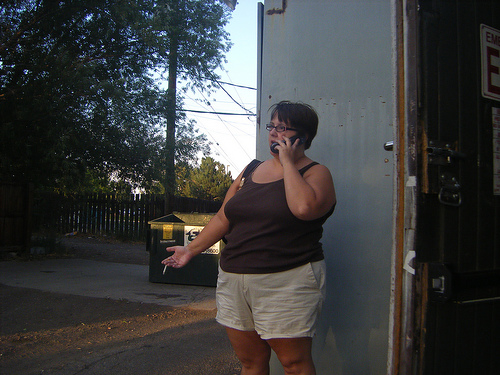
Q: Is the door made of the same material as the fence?
A: Yes, both the door and the fence are made of wood.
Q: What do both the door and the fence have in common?
A: The material, both the door and the fence are wooden.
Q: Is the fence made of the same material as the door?
A: Yes, both the fence and the door are made of wood.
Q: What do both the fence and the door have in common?
A: The material, both the fence and the door are wooden.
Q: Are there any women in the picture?
A: Yes, there is a woman.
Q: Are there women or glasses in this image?
A: Yes, there is a woman.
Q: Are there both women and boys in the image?
A: No, there is a woman but no boys.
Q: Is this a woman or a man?
A: This is a woman.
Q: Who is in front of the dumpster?
A: The woman is in front of the dumpster.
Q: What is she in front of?
A: The woman is in front of the dumpster.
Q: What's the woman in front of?
A: The woman is in front of the dumpster.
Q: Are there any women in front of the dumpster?
A: Yes, there is a woman in front of the dumpster.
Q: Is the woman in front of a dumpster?
A: Yes, the woman is in front of a dumpster.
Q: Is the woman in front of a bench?
A: No, the woman is in front of a dumpster.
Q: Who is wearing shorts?
A: The woman is wearing shorts.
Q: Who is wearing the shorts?
A: The woman is wearing shorts.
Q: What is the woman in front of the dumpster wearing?
A: The woman is wearing shorts.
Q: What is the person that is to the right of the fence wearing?
A: The woman is wearing shorts.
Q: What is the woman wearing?
A: The woman is wearing shorts.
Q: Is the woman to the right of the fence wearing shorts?
A: Yes, the woman is wearing shorts.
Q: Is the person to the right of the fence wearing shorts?
A: Yes, the woman is wearing shorts.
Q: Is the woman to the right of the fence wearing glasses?
A: No, the woman is wearing shorts.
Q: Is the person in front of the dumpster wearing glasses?
A: No, the woman is wearing shorts.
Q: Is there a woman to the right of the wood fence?
A: Yes, there is a woman to the right of the fence.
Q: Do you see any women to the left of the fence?
A: No, the woman is to the right of the fence.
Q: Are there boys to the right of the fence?
A: No, there is a woman to the right of the fence.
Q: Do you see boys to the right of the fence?
A: No, there is a woman to the right of the fence.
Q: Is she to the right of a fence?
A: Yes, the woman is to the right of a fence.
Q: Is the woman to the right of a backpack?
A: No, the woman is to the right of a fence.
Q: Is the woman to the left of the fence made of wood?
A: No, the woman is to the right of the fence.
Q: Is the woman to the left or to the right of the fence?
A: The woman is to the right of the fence.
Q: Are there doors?
A: Yes, there is a door.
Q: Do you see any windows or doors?
A: Yes, there is a door.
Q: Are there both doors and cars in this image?
A: No, there is a door but no cars.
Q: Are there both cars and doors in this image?
A: No, there is a door but no cars.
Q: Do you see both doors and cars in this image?
A: No, there is a door but no cars.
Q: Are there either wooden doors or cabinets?
A: Yes, there is a wood door.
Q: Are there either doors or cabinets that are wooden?
A: Yes, the door is wooden.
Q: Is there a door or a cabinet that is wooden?
A: Yes, the door is wooden.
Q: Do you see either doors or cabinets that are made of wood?
A: Yes, the door is made of wood.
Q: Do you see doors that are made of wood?
A: Yes, there is a door that is made of wood.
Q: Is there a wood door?
A: Yes, there is a door that is made of wood.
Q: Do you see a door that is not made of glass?
A: Yes, there is a door that is made of wood.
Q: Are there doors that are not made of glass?
A: Yes, there is a door that is made of wood.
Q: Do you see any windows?
A: No, there are no windows.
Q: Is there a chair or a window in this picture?
A: No, there are no windows or chairs.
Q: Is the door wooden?
A: Yes, the door is wooden.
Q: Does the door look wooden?
A: Yes, the door is wooden.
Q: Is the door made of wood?
A: Yes, the door is made of wood.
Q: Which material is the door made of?
A: The door is made of wood.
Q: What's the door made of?
A: The door is made of wood.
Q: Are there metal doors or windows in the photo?
A: No, there is a door but it is wooden.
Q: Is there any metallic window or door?
A: No, there is a door but it is wooden.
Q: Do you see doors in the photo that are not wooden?
A: No, there is a door but it is wooden.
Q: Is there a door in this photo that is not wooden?
A: No, there is a door but it is wooden.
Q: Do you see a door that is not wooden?
A: No, there is a door but it is wooden.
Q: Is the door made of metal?
A: No, the door is made of wood.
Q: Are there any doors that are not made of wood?
A: No, there is a door but it is made of wood.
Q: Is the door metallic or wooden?
A: The door is wooden.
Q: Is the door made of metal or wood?
A: The door is made of wood.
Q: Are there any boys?
A: No, there are no boys.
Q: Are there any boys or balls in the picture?
A: No, there are no boys or balls.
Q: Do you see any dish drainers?
A: No, there are no dish drainers.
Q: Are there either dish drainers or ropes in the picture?
A: No, there are no dish drainers or ropes.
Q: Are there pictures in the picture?
A: No, there are no pictures.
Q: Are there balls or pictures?
A: No, there are no pictures or balls.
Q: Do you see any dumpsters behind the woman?
A: Yes, there is a dumpster behind the woman.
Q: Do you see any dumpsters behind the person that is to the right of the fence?
A: Yes, there is a dumpster behind the woman.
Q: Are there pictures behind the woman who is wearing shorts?
A: No, there is a dumpster behind the woman.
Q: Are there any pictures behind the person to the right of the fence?
A: No, there is a dumpster behind the woman.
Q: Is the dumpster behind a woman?
A: Yes, the dumpster is behind a woman.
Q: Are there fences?
A: Yes, there is a fence.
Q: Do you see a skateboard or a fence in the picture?
A: Yes, there is a fence.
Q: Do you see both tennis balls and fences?
A: No, there is a fence but no tennis balls.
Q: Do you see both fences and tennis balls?
A: No, there is a fence but no tennis balls.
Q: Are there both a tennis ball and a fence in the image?
A: No, there is a fence but no tennis balls.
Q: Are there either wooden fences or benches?
A: Yes, there is a wood fence.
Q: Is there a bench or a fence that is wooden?
A: Yes, the fence is wooden.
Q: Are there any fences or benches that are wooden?
A: Yes, the fence is wooden.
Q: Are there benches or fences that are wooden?
A: Yes, the fence is wooden.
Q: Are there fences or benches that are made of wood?
A: Yes, the fence is made of wood.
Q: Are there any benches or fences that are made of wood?
A: Yes, the fence is made of wood.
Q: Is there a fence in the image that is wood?
A: Yes, there is a wood fence.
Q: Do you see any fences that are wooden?
A: Yes, there is a fence that is wooden.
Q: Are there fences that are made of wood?
A: Yes, there is a fence that is made of wood.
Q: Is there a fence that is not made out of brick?
A: Yes, there is a fence that is made of wood.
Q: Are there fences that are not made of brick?
A: Yes, there is a fence that is made of wood.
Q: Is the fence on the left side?
A: Yes, the fence is on the left of the image.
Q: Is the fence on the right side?
A: No, the fence is on the left of the image.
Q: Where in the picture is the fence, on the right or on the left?
A: The fence is on the left of the image.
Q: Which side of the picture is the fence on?
A: The fence is on the left of the image.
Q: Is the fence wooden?
A: Yes, the fence is wooden.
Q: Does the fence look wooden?
A: Yes, the fence is wooden.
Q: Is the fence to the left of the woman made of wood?
A: Yes, the fence is made of wood.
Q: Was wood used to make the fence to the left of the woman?
A: Yes, the fence is made of wood.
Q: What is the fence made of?
A: The fence is made of wood.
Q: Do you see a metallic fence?
A: No, there is a fence but it is wooden.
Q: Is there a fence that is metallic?
A: No, there is a fence but it is wooden.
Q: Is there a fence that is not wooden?
A: No, there is a fence but it is wooden.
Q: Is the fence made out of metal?
A: No, the fence is made of wood.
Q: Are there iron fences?
A: No, there is a fence but it is made of wood.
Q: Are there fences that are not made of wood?
A: No, there is a fence but it is made of wood.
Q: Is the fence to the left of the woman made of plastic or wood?
A: The fence is made of wood.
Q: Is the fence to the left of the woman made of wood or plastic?
A: The fence is made of wood.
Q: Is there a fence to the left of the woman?
A: Yes, there is a fence to the left of the woman.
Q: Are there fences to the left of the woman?
A: Yes, there is a fence to the left of the woman.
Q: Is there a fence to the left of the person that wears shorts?
A: Yes, there is a fence to the left of the woman.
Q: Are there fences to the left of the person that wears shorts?
A: Yes, there is a fence to the left of the woman.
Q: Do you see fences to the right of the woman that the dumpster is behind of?
A: No, the fence is to the left of the woman.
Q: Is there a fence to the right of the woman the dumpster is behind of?
A: No, the fence is to the left of the woman.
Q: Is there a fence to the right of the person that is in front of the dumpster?
A: No, the fence is to the left of the woman.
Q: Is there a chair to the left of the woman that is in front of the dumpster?
A: No, there is a fence to the left of the woman.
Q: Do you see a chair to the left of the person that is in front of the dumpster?
A: No, there is a fence to the left of the woman.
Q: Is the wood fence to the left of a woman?
A: Yes, the fence is to the left of a woman.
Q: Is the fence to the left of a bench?
A: No, the fence is to the left of a woman.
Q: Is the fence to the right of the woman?
A: No, the fence is to the left of the woman.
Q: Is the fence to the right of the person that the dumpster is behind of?
A: No, the fence is to the left of the woman.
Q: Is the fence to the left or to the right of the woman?
A: The fence is to the left of the woman.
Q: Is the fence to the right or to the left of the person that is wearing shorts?
A: The fence is to the left of the woman.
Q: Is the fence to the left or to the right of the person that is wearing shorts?
A: The fence is to the left of the woman.